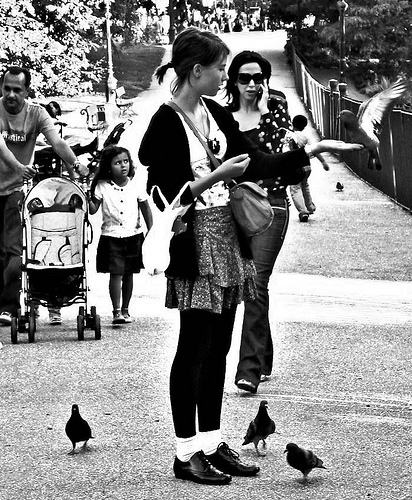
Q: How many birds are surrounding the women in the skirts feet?
A: Three.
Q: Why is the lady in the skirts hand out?
A: Feeding a bird.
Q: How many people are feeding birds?
A: One.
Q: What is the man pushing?
A: A stroller.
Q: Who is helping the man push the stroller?
A: Little girl.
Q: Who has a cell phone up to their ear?
A: Lady in polka dots.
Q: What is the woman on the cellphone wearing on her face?
A: Sunglasses.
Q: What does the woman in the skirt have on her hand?
A: A bird.